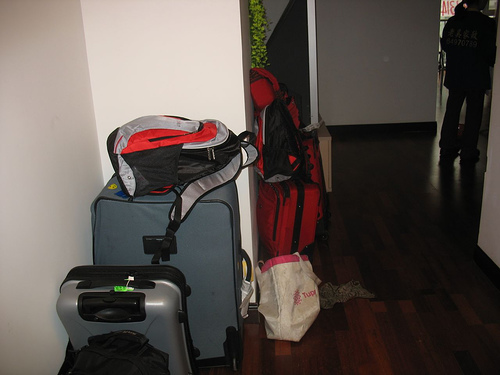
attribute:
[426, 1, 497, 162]
woman — close, standing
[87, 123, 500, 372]
floor — wooden, brown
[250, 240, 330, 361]
bag — small, pink, white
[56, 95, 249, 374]
luggage — black, silver, red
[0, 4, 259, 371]
wall — white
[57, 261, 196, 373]
suitcase — packed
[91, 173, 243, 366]
suitcase — packed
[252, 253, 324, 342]
bag — packed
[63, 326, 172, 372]
bag — packed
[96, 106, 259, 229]
backpack — black, red and grey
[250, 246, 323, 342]
shopping bag — pink and white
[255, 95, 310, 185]
backpack — red and black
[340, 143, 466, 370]
hardwood floor — dark brown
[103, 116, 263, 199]
backpack — red, gray, and black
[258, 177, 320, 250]
luggage — red and black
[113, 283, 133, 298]
tag — lime green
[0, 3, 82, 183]
wall — white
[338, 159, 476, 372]
floor — wood, brown